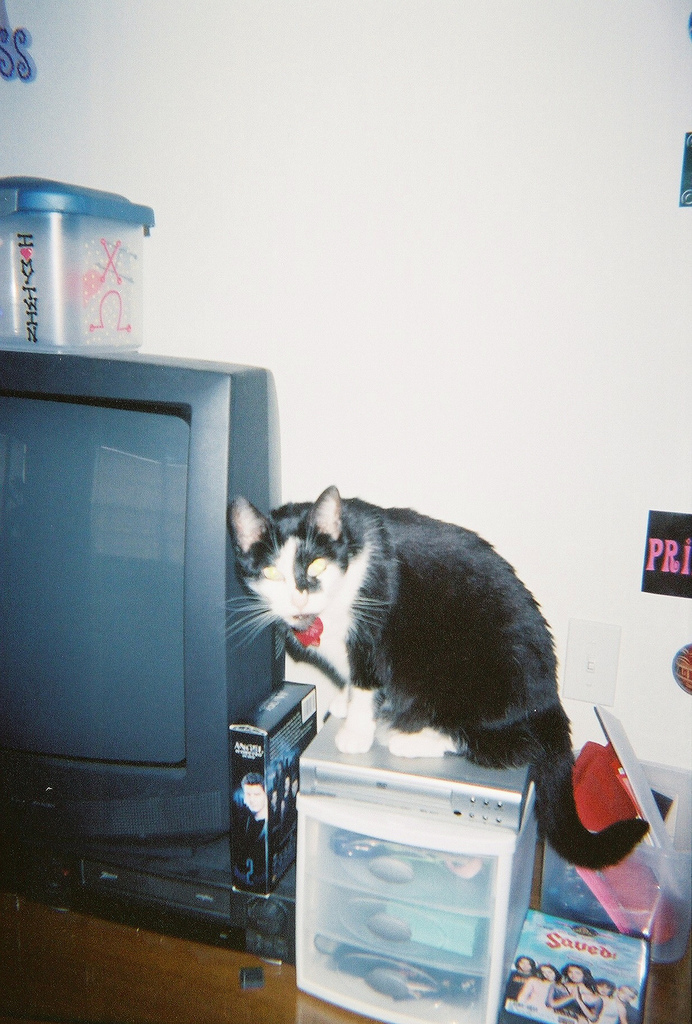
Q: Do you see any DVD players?
A: Yes, there is a DVD player.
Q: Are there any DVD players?
A: Yes, there is a DVD player.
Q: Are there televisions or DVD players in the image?
A: Yes, there is a DVD player.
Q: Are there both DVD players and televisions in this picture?
A: Yes, there are both a DVD player and a television.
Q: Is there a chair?
A: No, there are no chairs.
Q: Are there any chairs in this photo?
A: No, there are no chairs.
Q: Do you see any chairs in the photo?
A: No, there are no chairs.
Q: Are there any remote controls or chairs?
A: No, there are no chairs or remote controls.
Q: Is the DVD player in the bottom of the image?
A: Yes, the DVD player is in the bottom of the image.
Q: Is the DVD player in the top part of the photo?
A: No, the DVD player is in the bottom of the image.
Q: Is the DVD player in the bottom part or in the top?
A: The DVD player is in the bottom of the image.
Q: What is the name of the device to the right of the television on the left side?
A: The device is a DVD player.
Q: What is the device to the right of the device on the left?
A: The device is a DVD player.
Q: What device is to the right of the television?
A: The device is a DVD player.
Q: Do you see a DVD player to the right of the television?
A: Yes, there is a DVD player to the right of the television.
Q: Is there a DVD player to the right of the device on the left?
A: Yes, there is a DVD player to the right of the television.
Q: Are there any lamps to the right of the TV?
A: No, there is a DVD player to the right of the TV.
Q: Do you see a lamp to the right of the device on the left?
A: No, there is a DVD player to the right of the TV.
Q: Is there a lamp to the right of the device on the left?
A: No, there is a DVD player to the right of the TV.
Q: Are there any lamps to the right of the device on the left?
A: No, there is a DVD player to the right of the TV.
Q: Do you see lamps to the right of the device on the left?
A: No, there is a DVD player to the right of the TV.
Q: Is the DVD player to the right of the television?
A: Yes, the DVD player is to the right of the television.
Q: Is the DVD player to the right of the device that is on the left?
A: Yes, the DVD player is to the right of the television.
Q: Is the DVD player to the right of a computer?
A: No, the DVD player is to the right of the television.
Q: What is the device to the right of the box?
A: The device is a DVD player.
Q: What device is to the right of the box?
A: The device is a DVD player.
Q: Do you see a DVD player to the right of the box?
A: Yes, there is a DVD player to the right of the box.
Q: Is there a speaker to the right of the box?
A: No, there is a DVD player to the right of the box.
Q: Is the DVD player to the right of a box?
A: Yes, the DVD player is to the right of a box.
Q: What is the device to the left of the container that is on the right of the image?
A: The device is a DVD player.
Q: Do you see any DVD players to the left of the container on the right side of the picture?
A: Yes, there is a DVD player to the left of the container.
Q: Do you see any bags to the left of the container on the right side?
A: No, there is a DVD player to the left of the container.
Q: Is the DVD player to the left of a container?
A: Yes, the DVD player is to the left of a container.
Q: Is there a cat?
A: Yes, there is a cat.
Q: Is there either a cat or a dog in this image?
A: Yes, there is a cat.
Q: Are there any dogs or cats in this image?
A: Yes, there is a cat.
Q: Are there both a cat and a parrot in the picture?
A: No, there is a cat but no parrots.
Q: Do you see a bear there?
A: No, there are no bears.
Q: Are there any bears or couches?
A: No, there are no bears or couches.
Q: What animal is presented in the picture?
A: The animal is a cat.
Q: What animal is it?
A: The animal is a cat.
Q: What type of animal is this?
A: This is a cat.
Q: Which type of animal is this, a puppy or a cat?
A: This is a cat.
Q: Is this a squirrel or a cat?
A: This is a cat.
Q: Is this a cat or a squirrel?
A: This is a cat.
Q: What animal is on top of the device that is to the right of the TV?
A: The cat is on top of the DVD player.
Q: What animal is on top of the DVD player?
A: The cat is on top of the DVD player.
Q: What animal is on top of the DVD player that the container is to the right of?
A: The animal is a cat.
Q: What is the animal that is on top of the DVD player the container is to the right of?
A: The animal is a cat.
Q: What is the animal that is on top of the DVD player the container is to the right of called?
A: The animal is a cat.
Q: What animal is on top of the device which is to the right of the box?
A: The animal is a cat.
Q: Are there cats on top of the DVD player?
A: Yes, there is a cat on top of the DVD player.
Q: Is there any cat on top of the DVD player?
A: Yes, there is a cat on top of the DVD player.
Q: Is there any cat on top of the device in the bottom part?
A: Yes, there is a cat on top of the DVD player.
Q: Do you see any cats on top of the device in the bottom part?
A: Yes, there is a cat on top of the DVD player.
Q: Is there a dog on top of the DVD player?
A: No, there is a cat on top of the DVD player.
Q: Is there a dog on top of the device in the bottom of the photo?
A: No, there is a cat on top of the DVD player.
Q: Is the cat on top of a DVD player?
A: Yes, the cat is on top of a DVD player.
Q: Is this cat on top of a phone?
A: No, the cat is on top of a DVD player.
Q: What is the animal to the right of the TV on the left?
A: The animal is a cat.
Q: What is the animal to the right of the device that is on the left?
A: The animal is a cat.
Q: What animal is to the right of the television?
A: The animal is a cat.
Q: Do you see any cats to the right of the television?
A: Yes, there is a cat to the right of the television.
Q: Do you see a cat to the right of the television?
A: Yes, there is a cat to the right of the television.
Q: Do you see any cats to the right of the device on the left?
A: Yes, there is a cat to the right of the television.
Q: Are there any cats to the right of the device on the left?
A: Yes, there is a cat to the right of the television.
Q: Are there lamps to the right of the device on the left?
A: No, there is a cat to the right of the TV.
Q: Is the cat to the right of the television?
A: Yes, the cat is to the right of the television.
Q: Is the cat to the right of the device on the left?
A: Yes, the cat is to the right of the television.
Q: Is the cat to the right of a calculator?
A: No, the cat is to the right of the television.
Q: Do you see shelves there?
A: No, there are no shelves.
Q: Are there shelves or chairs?
A: No, there are no shelves or chairs.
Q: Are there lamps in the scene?
A: No, there are no lamps.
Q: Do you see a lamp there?
A: No, there are no lamps.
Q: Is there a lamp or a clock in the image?
A: No, there are no lamps or clocks.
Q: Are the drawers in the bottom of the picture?
A: Yes, the drawers are in the bottom of the image.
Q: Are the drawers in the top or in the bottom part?
A: The drawers are in the bottom of the image.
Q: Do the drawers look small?
A: Yes, the drawers are small.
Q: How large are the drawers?
A: The drawers are small.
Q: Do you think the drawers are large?
A: No, the drawers are small.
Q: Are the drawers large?
A: No, the drawers are small.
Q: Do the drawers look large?
A: No, the drawers are small.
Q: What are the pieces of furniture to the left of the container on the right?
A: The pieces of furniture are drawers.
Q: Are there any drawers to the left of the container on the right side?
A: Yes, there are drawers to the left of the container.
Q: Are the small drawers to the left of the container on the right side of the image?
A: Yes, the drawers are to the left of the container.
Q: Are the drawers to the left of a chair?
A: No, the drawers are to the left of the container.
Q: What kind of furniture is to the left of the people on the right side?
A: The pieces of furniture are drawers.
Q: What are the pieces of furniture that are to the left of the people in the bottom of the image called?
A: The pieces of furniture are drawers.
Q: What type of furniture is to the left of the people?
A: The pieces of furniture are drawers.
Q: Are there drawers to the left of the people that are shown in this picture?
A: Yes, there are drawers to the left of the people.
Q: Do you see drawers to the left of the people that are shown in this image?
A: Yes, there are drawers to the left of the people.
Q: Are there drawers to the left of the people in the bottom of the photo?
A: Yes, there are drawers to the left of the people.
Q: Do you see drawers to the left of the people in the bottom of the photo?
A: Yes, there are drawers to the left of the people.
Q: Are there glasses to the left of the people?
A: No, there are drawers to the left of the people.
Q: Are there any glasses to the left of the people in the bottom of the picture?
A: No, there are drawers to the left of the people.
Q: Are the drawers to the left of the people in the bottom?
A: Yes, the drawers are to the left of the people.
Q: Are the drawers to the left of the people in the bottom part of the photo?
A: Yes, the drawers are to the left of the people.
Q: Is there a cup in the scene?
A: No, there are no cups.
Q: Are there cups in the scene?
A: No, there are no cups.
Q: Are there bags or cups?
A: No, there are no cups or bags.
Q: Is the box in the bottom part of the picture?
A: Yes, the box is in the bottom of the image.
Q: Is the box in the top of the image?
A: No, the box is in the bottom of the image.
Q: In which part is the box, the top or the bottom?
A: The box is in the bottom of the image.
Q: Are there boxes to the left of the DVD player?
A: Yes, there is a box to the left of the DVD player.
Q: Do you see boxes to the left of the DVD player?
A: Yes, there is a box to the left of the DVD player.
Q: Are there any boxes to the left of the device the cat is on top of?
A: Yes, there is a box to the left of the DVD player.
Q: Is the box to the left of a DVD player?
A: Yes, the box is to the left of a DVD player.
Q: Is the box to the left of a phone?
A: No, the box is to the left of a DVD player.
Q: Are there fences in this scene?
A: No, there are no fences.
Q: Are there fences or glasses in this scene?
A: No, there are no fences or glasses.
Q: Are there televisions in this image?
A: Yes, there is a television.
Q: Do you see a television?
A: Yes, there is a television.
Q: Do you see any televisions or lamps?
A: Yes, there is a television.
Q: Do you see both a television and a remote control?
A: No, there is a television but no remote controls.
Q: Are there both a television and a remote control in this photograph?
A: No, there is a television but no remote controls.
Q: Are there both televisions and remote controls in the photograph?
A: No, there is a television but no remote controls.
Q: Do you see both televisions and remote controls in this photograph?
A: No, there is a television but no remote controls.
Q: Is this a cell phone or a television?
A: This is a television.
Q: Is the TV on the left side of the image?
A: Yes, the TV is on the left of the image.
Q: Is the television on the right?
A: No, the television is on the left of the image.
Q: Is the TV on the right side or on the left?
A: The TV is on the left of the image.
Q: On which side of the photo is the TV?
A: The TV is on the left of the image.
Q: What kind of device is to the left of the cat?
A: The device is a television.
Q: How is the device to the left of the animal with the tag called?
A: The device is a television.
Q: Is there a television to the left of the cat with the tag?
A: Yes, there is a television to the left of the cat.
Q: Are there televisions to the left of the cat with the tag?
A: Yes, there is a television to the left of the cat.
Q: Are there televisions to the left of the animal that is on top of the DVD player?
A: Yes, there is a television to the left of the cat.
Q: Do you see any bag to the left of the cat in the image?
A: No, there is a television to the left of the cat.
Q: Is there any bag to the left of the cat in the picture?
A: No, there is a television to the left of the cat.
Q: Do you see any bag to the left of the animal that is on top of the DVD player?
A: No, there is a television to the left of the cat.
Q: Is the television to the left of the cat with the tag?
A: Yes, the television is to the left of the cat.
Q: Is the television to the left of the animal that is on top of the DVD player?
A: Yes, the television is to the left of the cat.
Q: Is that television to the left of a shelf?
A: No, the television is to the left of the cat.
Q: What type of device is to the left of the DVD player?
A: The device is a television.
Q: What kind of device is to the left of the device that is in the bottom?
A: The device is a television.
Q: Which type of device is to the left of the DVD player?
A: The device is a television.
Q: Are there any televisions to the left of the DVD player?
A: Yes, there is a television to the left of the DVD player.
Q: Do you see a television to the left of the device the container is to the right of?
A: Yes, there is a television to the left of the DVD player.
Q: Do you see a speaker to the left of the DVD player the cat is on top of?
A: No, there is a television to the left of the DVD player.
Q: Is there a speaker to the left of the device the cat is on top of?
A: No, there is a television to the left of the DVD player.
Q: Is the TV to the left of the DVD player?
A: Yes, the TV is to the left of the DVD player.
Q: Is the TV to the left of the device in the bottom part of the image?
A: Yes, the TV is to the left of the DVD player.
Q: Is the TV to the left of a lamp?
A: No, the TV is to the left of the DVD player.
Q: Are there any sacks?
A: No, there are no sacks.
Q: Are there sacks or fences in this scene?
A: No, there are no sacks or fences.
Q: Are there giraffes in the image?
A: No, there are no giraffes.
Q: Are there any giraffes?
A: No, there are no giraffes.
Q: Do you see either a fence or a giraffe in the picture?
A: No, there are no giraffes or fences.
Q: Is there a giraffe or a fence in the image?
A: No, there are no giraffes or fences.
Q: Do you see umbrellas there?
A: No, there are no umbrellas.